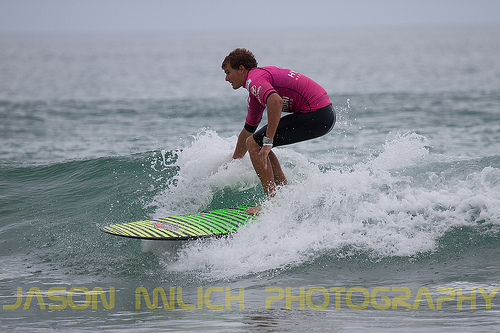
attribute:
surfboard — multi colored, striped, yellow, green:
[100, 203, 262, 241]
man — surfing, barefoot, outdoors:
[223, 48, 338, 214]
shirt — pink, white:
[244, 66, 333, 132]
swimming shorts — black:
[253, 103, 337, 149]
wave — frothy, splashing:
[1, 99, 500, 331]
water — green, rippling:
[2, 21, 499, 330]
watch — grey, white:
[262, 136, 274, 146]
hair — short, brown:
[222, 47, 260, 73]